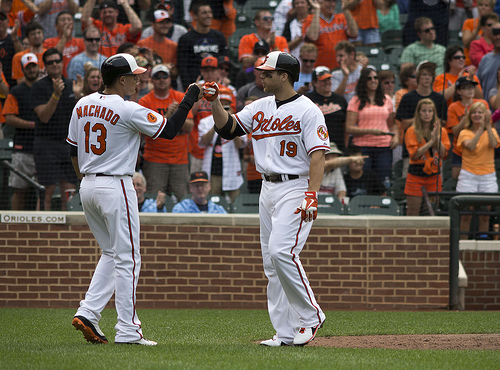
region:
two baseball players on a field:
[63, 48, 336, 348]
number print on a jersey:
[78, 119, 108, 156]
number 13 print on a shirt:
[76, 119, 108, 156]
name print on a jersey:
[73, 103, 121, 124]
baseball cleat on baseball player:
[68, 314, 110, 342]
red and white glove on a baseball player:
[293, 188, 323, 223]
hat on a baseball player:
[253, 50, 305, 82]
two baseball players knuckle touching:
[63, 49, 334, 351]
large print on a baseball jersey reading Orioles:
[248, 109, 303, 141]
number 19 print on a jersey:
[277, 138, 299, 160]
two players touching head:
[173, 59, 223, 105]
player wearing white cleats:
[235, 302, 327, 349]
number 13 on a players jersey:
[67, 114, 115, 161]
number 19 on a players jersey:
[278, 138, 301, 163]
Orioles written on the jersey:
[243, 105, 307, 139]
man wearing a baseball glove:
[301, 188, 328, 228]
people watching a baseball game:
[336, 33, 498, 183]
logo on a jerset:
[140, 109, 158, 127]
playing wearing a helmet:
[93, 40, 147, 82]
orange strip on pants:
[109, 169, 153, 351]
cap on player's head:
[257, 50, 299, 80]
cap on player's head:
[99, 49, 156, 75]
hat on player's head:
[96, 54, 141, 75]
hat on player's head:
[250, 50, 300, 77]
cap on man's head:
[256, 48, 299, 77]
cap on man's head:
[97, 55, 157, 75]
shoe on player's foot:
[113, 334, 156, 350]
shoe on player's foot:
[69, 311, 106, 342]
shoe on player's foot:
[290, 315, 327, 348]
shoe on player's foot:
[261, 328, 291, 345]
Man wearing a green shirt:
[400, 18, 445, 73]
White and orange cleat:
[295, 310, 325, 347]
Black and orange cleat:
[72, 314, 106, 342]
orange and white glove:
[295, 189, 316, 221]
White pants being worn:
[73, 175, 143, 342]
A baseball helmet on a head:
[254, 50, 301, 80]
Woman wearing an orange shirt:
[404, 99, 449, 214]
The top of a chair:
[348, 195, 400, 214]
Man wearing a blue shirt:
[174, 170, 229, 213]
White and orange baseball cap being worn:
[20, 50, 37, 65]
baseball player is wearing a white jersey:
[66, 49, 208, 354]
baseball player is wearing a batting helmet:
[57, 42, 202, 348]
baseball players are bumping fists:
[57, 42, 340, 349]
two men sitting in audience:
[119, 163, 236, 235]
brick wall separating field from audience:
[0, 203, 457, 316]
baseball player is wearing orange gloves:
[198, 45, 340, 352]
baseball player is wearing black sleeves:
[59, 44, 206, 351]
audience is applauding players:
[2, 0, 494, 210]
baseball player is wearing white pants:
[65, 45, 207, 349]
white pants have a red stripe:
[69, 170, 168, 354]